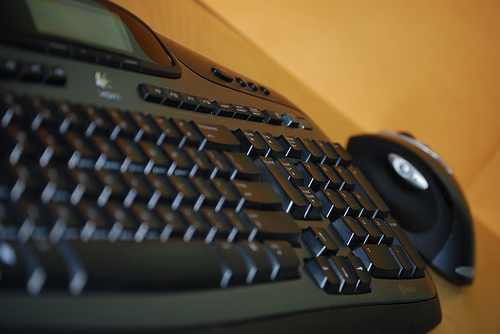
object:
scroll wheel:
[396, 129, 415, 139]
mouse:
[345, 128, 479, 287]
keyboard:
[0, 0, 442, 332]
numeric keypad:
[275, 130, 431, 282]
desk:
[105, 0, 499, 333]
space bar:
[50, 240, 223, 298]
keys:
[186, 115, 242, 151]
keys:
[218, 147, 265, 182]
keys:
[232, 178, 283, 213]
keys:
[240, 204, 303, 247]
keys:
[210, 236, 250, 290]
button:
[396, 161, 410, 176]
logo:
[90, 70, 123, 103]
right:
[325, 104, 497, 277]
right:
[344, 251, 374, 296]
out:
[0, 54, 433, 306]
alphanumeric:
[204, 205, 224, 229]